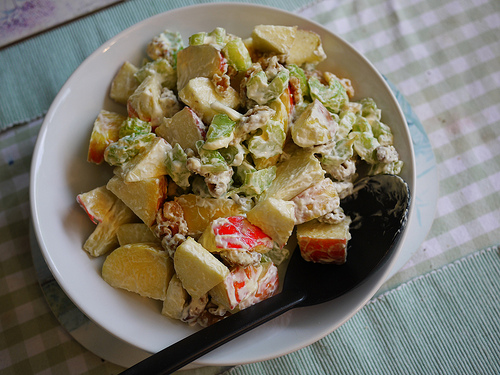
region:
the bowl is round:
[3, 1, 413, 364]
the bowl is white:
[0, 3, 440, 373]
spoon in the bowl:
[109, 111, 468, 356]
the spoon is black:
[143, 196, 497, 362]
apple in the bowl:
[271, 201, 369, 277]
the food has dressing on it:
[57, 33, 495, 341]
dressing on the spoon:
[331, 148, 448, 270]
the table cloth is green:
[1, 9, 497, 365]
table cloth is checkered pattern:
[315, 3, 497, 152]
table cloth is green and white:
[346, 6, 495, 292]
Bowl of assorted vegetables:
[28, 3, 418, 363]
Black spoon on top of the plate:
[122, 173, 403, 373]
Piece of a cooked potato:
[295, 219, 349, 260]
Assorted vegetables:
[71, 23, 402, 330]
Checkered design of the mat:
[417, 19, 475, 66]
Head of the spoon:
[284, 172, 409, 309]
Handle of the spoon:
[127, 289, 305, 371]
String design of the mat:
[230, 245, 498, 373]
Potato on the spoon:
[295, 218, 356, 268]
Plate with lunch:
[25, 5, 413, 365]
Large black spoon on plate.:
[246, 212, 433, 322]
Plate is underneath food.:
[45, 24, 395, 332]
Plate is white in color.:
[61, 43, 390, 327]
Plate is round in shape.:
[43, 65, 365, 372]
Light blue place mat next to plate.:
[390, 271, 466, 367]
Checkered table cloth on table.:
[392, 20, 488, 164]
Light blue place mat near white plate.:
[13, 49, 62, 104]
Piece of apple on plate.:
[296, 228, 351, 264]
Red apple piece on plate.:
[206, 227, 268, 259]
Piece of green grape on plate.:
[206, 104, 241, 146]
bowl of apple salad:
[23, 4, 416, 362]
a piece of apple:
[211, 210, 268, 256]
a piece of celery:
[248, 115, 279, 155]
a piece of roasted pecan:
[152, 200, 186, 252]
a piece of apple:
[101, 235, 167, 292]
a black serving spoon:
[170, 170, 410, 373]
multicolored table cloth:
[13, 2, 496, 353]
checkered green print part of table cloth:
[426, 6, 486, 271]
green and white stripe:
[381, 260, 496, 372]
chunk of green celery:
[305, 75, 351, 110]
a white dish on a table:
[25, 5, 425, 374]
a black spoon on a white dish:
[126, 168, 416, 374]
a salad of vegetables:
[67, 18, 405, 335]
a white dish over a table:
[1, 0, 497, 372]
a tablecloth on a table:
[5, 4, 497, 374]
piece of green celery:
[294, 67, 349, 116]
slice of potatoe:
[175, 68, 252, 134]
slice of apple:
[193, 208, 269, 256]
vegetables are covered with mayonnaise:
[61, 13, 401, 347]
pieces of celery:
[102, 109, 161, 162]